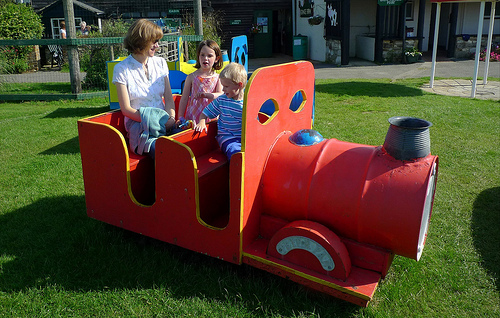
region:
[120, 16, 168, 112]
this is a person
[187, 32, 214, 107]
this is a chid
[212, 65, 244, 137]
this is a chid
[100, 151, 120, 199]
this is orange colour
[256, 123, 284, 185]
this is orange colour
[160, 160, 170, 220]
this is orange colour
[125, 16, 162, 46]
this is a head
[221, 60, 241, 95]
this is a head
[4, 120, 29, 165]
the grass is short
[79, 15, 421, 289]
family sitting on red train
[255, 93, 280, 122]
small window in train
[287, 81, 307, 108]
small window in train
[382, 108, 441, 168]
black smokestack on train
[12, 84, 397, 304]
grass growing on playground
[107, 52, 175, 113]
white shirt on mother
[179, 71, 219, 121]
pink dress on daughter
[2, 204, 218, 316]
shadow of train on grass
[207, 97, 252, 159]
blue shirt on son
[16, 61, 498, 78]
paved road in background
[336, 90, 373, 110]
well cared for green grass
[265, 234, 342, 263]
semi circular white sign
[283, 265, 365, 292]
yellow color on side of train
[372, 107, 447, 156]
small spout on front of train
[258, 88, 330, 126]
cut out design on train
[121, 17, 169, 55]
woman with short brown hair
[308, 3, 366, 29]
small white animal on wall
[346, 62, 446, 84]
gray color on the sidewalk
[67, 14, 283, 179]
people sitting in the train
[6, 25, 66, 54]
green post in the background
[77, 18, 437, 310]
woman and children sitting in toy train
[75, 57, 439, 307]
red wooden train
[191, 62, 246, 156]
boy in blue striped shirt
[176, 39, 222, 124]
girl with red hair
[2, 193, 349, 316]
shadow cast by train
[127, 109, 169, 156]
blue sweater draped over woman's arm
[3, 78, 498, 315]
green grass in park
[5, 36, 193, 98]
green and grey fence behind train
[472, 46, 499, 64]
cluster of pink flowers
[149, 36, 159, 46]
dark glasses on face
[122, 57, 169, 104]
the shirt is white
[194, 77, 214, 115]
the dress is pink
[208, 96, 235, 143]
the shirt is blue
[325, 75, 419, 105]
shadow is on the ground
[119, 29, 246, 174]
the people are in a toy train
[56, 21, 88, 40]
people are in the background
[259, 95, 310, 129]
eyes are on the wood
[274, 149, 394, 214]
the tank is red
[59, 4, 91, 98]
the tree post is brown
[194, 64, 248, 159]
little blond kid wearing striped blue shirt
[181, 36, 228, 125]
little red haired girl standing inside wagon train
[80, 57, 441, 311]
black and red wagon train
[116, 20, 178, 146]
woman wearing white shirt sitting in red wagon train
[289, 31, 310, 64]
round green trash can in the background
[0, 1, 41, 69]
green bushes in the background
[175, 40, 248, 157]
kids sittinf in red wagno train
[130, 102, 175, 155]
blue sweater on right arm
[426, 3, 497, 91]
white poles in round concrete area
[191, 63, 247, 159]
boy has blond hair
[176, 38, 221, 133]
girl sitting behind the boy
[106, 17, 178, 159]
woman is sitting next to the girl